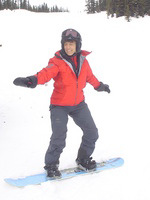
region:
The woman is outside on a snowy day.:
[1, 0, 146, 198]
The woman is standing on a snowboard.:
[3, 24, 123, 189]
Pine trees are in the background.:
[87, 0, 148, 16]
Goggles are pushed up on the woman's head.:
[60, 25, 78, 37]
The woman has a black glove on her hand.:
[12, 73, 36, 88]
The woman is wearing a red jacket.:
[36, 51, 93, 106]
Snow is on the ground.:
[111, 43, 138, 92]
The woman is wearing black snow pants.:
[39, 100, 93, 163]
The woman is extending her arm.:
[10, 57, 55, 90]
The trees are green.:
[0, 0, 69, 9]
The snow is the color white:
[106, 102, 146, 147]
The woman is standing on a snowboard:
[0, 156, 126, 186]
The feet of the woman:
[39, 156, 93, 177]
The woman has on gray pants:
[42, 99, 96, 168]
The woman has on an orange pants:
[33, 48, 96, 105]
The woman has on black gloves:
[9, 72, 36, 87]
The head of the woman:
[58, 27, 82, 57]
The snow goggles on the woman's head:
[60, 27, 82, 40]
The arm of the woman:
[11, 58, 66, 88]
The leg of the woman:
[74, 110, 99, 158]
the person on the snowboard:
[15, 27, 119, 178]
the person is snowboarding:
[10, 25, 114, 184]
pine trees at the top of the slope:
[6, 0, 147, 16]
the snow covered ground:
[15, 14, 127, 39]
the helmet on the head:
[45, 27, 91, 60]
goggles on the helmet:
[56, 28, 89, 39]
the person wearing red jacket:
[32, 49, 92, 107]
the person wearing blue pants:
[47, 98, 99, 158]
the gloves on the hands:
[11, 75, 117, 95]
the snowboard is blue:
[2, 155, 126, 187]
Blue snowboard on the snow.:
[3, 155, 123, 190]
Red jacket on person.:
[33, 26, 100, 105]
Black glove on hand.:
[12, 74, 39, 89]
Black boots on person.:
[43, 156, 97, 179]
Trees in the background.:
[85, 0, 149, 22]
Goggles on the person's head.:
[58, 28, 84, 54]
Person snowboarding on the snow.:
[4, 21, 124, 193]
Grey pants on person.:
[45, 26, 100, 181]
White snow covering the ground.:
[0, 9, 149, 196]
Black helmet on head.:
[58, 27, 83, 55]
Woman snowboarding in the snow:
[10, 27, 133, 194]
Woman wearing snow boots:
[36, 145, 108, 183]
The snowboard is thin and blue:
[14, 152, 136, 190]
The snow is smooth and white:
[15, 113, 43, 151]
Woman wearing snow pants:
[40, 94, 104, 167]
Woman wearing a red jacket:
[32, 53, 101, 112]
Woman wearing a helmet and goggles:
[60, 23, 86, 60]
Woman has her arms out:
[10, 58, 118, 107]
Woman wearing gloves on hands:
[91, 81, 111, 98]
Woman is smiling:
[56, 41, 80, 56]